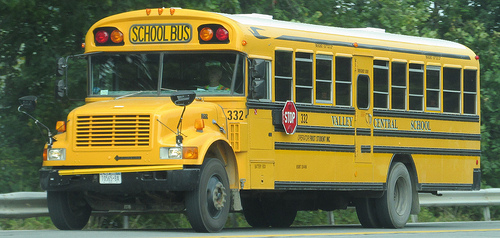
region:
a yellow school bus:
[41, 6, 481, 231]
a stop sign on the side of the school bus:
[280, 97, 296, 132]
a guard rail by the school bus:
[0, 185, 495, 215]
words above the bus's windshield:
[127, 20, 188, 42]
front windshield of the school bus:
[87, 50, 239, 90]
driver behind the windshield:
[197, 56, 227, 91]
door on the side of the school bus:
[350, 50, 372, 160]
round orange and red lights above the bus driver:
[197, 25, 227, 40]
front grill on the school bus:
[72, 111, 148, 146]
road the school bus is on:
[0, 220, 497, 236]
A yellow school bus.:
[15, 5, 482, 233]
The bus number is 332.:
[225, 108, 245, 123]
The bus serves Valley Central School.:
[329, 113, 434, 132]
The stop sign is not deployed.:
[278, 98, 300, 136]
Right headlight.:
[158, 144, 198, 161]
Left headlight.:
[41, 148, 67, 162]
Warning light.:
[196, 20, 232, 47]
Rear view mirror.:
[168, 90, 195, 146]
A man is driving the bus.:
[197, 56, 234, 96]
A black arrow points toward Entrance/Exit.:
[112, 152, 143, 164]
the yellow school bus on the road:
[19, 7, 481, 229]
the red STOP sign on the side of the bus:
[282, 99, 297, 134]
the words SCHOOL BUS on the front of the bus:
[131, 23, 191, 42]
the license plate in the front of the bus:
[101, 174, 121, 182]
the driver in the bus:
[203, 65, 226, 92]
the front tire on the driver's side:
[183, 153, 231, 230]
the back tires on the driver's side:
[358, 160, 413, 228]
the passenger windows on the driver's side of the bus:
[273, 47, 477, 117]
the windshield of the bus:
[86, 50, 243, 92]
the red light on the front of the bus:
[216, 27, 228, 40]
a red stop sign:
[280, 98, 299, 135]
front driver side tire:
[184, 155, 231, 232]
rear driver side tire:
[358, 163, 413, 228]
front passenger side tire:
[44, 170, 90, 230]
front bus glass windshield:
[86, 53, 242, 93]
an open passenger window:
[274, 49, 291, 102]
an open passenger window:
[294, 53, 312, 104]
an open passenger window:
[407, 60, 426, 106]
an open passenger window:
[372, 55, 388, 106]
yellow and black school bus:
[29, 9, 490, 229]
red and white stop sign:
[274, 101, 306, 136]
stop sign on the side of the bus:
[269, 102, 309, 135]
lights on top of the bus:
[87, 20, 227, 48]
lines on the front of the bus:
[66, 108, 157, 153]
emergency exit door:
[348, 56, 379, 171]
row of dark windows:
[272, 47, 482, 122]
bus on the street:
[32, 6, 492, 230]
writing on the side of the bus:
[328, 112, 447, 130]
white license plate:
[96, 169, 130, 187]